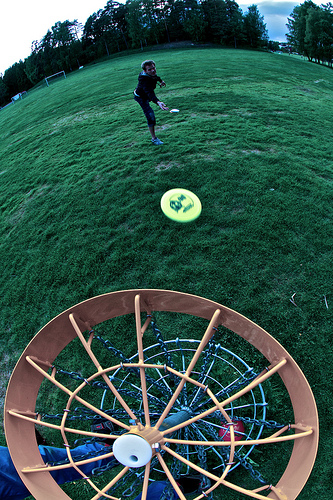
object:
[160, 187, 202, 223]
frisbee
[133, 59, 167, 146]
man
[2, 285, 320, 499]
goal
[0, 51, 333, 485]
field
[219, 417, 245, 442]
ball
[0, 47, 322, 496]
grass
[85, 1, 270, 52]
bush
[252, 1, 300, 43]
cloud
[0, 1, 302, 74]
sky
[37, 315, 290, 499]
chains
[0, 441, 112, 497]
pant